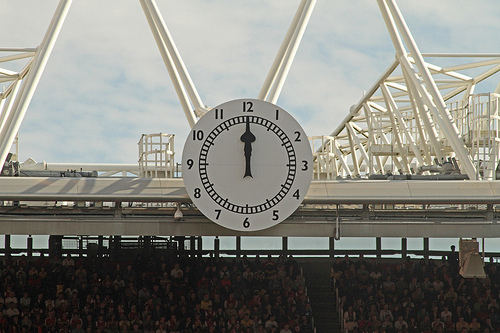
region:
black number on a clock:
[271, 103, 283, 123]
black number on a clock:
[287, 128, 302, 144]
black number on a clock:
[299, 157, 311, 176]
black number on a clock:
[290, 185, 302, 200]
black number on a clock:
[269, 203, 281, 225]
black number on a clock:
[239, 213, 250, 230]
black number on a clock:
[212, 206, 224, 223]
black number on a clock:
[191, 181, 201, 202]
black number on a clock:
[184, 157, 198, 172]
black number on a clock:
[190, 121, 206, 145]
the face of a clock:
[180, 98, 312, 231]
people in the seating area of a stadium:
[49, 261, 273, 323]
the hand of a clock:
[234, 116, 259, 183]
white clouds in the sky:
[83, 70, 137, 125]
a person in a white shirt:
[167, 264, 187, 276]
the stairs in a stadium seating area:
[300, 262, 342, 330]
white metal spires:
[264, 6, 438, 96]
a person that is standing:
[441, 243, 458, 270]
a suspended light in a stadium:
[447, 233, 492, 283]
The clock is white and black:
[179, 96, 312, 232]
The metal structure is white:
[3, 3, 493, 190]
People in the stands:
[7, 237, 492, 329]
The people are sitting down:
[18, 246, 490, 327]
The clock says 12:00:
[180, 96, 314, 233]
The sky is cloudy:
[29, 6, 392, 159]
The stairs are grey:
[299, 257, 350, 331]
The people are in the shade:
[8, 241, 493, 329]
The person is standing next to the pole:
[447, 242, 461, 263]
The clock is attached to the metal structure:
[178, 94, 318, 240]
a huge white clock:
[178, 95, 313, 231]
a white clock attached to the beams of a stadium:
[0, 1, 497, 236]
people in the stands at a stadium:
[4, 243, 498, 331]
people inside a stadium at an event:
[2, 244, 498, 331]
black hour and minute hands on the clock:
[238, 113, 257, 178]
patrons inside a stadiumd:
[1, 254, 498, 331]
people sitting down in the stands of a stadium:
[0, 252, 318, 331]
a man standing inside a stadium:
[447, 245, 459, 262]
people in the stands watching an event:
[1, 243, 445, 331]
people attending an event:
[2, 243, 499, 331]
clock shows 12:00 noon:
[173, 96, 314, 230]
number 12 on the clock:
[242, 98, 257, 114]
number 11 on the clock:
[208, 103, 230, 126]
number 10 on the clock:
[188, 128, 206, 141]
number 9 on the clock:
[183, 155, 201, 173]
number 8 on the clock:
[192, 185, 205, 202]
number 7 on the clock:
[209, 204, 228, 226]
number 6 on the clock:
[238, 213, 258, 235]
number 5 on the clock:
[269, 205, 283, 228]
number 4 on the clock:
[288, 185, 308, 205]